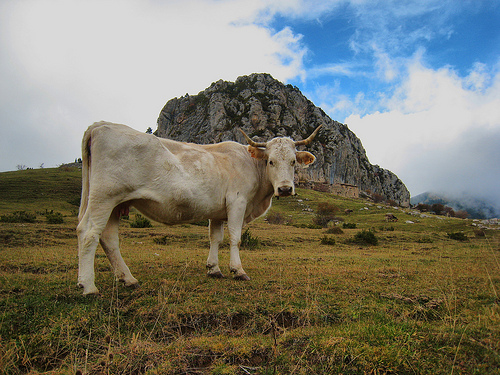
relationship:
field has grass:
[10, 197, 493, 372] [2, 217, 494, 369]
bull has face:
[72, 116, 305, 292] [258, 136, 310, 200]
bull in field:
[77, 120, 324, 299] [2, 171, 497, 372]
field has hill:
[0, 168, 499, 373] [152, 47, 366, 145]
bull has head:
[77, 120, 324, 299] [261, 135, 299, 194]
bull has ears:
[77, 120, 324, 299] [248, 145, 316, 167]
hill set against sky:
[152, 72, 413, 209] [0, 0, 499, 198]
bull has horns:
[77, 120, 324, 299] [232, 123, 347, 156]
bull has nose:
[77, 120, 324, 299] [261, 165, 301, 202]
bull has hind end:
[77, 120, 324, 299] [64, 110, 164, 240]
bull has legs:
[77, 120, 324, 299] [190, 210, 260, 284]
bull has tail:
[77, 120, 324, 299] [73, 120, 95, 219]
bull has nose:
[77, 120, 324, 299] [273, 172, 300, 208]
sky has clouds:
[392, 8, 496, 97] [386, 18, 459, 133]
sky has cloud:
[0, 0, 499, 198] [353, 60, 498, 195]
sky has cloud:
[0, 0, 499, 198] [2, 2, 343, 172]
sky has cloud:
[0, 0, 499, 198] [0, 0, 499, 219]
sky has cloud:
[0, 0, 499, 198] [307, 2, 481, 84]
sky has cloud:
[0, 0, 499, 198] [361, 42, 475, 164]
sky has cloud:
[0, 0, 499, 198] [337, 60, 497, 168]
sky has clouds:
[0, 0, 499, 198] [144, 14, 427, 64]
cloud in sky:
[0, 0, 499, 219] [324, 28, 379, 68]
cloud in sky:
[2, 4, 312, 169] [0, 0, 499, 196]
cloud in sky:
[0, 0, 499, 219] [0, 0, 499, 196]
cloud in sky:
[0, 0, 499, 219] [7, 5, 492, 216]